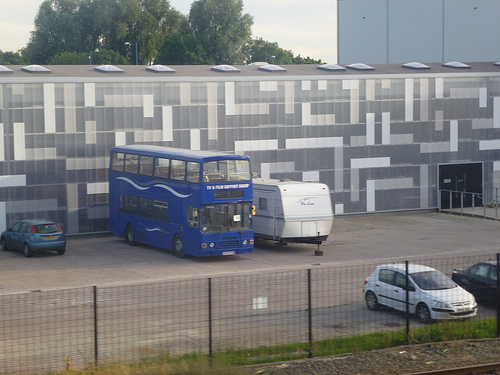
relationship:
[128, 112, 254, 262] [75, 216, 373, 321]
bus in lot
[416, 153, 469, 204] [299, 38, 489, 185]
door to building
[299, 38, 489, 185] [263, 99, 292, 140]
building has glass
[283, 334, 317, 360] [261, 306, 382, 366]
grass on ground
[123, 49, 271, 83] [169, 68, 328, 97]
skylights on roof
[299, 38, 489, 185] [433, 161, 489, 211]
building has door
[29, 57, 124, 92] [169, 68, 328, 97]
panels on roof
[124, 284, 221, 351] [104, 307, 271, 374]
wiring on gate